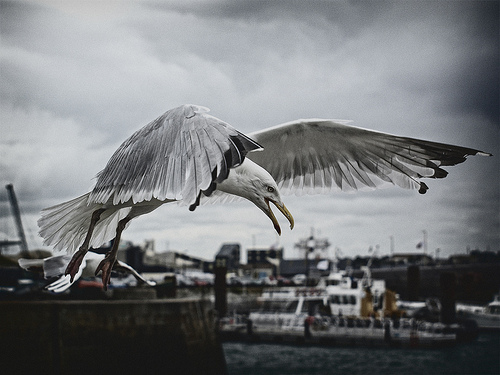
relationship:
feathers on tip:
[87, 86, 274, 239] [242, 134, 266, 157]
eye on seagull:
[262, 185, 277, 197] [30, 99, 495, 297]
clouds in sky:
[27, 17, 198, 115] [0, 0, 492, 239]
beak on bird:
[259, 193, 298, 237] [39, 103, 499, 262]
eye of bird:
[262, 185, 277, 197] [37, 102, 494, 298]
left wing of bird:
[235, 118, 496, 197] [37, 102, 494, 298]